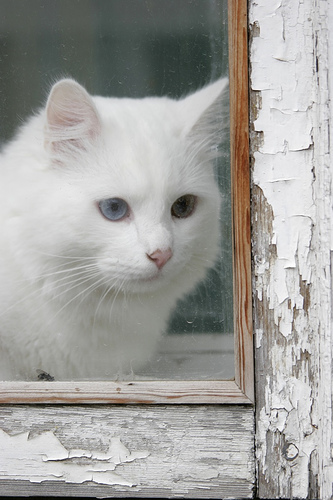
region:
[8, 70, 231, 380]
white cat behind glass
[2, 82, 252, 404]
wood frame around window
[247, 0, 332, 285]
peeling paint on wall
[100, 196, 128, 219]
blue eye of cat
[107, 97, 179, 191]
white fur on head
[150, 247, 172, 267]
pink nose on snout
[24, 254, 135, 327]
white whiskers on face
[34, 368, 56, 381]
fly on window frame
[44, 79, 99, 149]
ear on cat head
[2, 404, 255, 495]
worn wood under frame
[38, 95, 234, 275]
Cat inside a window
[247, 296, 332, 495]
Paint peeling on a window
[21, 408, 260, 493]
Paint peeling on a window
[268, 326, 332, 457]
Paint peeling on a window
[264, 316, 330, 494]
Wooden window frame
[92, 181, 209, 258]
white cat with blue eyes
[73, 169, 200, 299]
Cat with pink nose and whiskers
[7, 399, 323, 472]
gray window frame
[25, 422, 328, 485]
paint peeling on frame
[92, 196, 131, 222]
Light blue cat's eye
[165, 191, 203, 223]
Light green cat's eye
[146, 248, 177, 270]
Light pink cat's nose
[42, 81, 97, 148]
Light pink and white cat's ear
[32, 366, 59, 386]
Small fly on the windowsill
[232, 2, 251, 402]
Vertical windowsill beam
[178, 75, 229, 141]
White cat's ear next to the windowsill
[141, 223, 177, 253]
White bridge of the cat's nose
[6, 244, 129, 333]
White cat's whiskers in front of the window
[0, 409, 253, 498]
Patch of window with peeling paint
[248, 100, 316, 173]
Paint chipping on a window frame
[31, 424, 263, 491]
Paint chipping on a window frame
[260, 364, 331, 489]
Paint chipping on a window frame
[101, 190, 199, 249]
Cat with blue eyes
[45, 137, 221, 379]
cat looking out the window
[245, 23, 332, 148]
Paint chipping on a frame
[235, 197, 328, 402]
Wooding window frame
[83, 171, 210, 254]
Blue eyes with a cat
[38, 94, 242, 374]
Cats in front of a window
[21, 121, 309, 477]
Cat looking out a window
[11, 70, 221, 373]
this is a white fluffy cat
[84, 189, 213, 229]
these are the cats eyes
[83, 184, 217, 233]
the cats eyes are two different colors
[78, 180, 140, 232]
this eye is blue in color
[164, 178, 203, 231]
this eye is green in color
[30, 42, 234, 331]
the cat is looking through the window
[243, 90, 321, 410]
the window frame is made of wood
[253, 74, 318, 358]
the frame is covered in white chipped paint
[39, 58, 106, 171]
this is the cats ear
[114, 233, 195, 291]
this is the cats nose and mouth